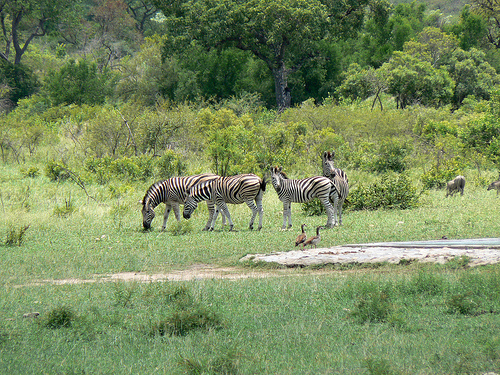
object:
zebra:
[319, 147, 351, 232]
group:
[132, 144, 365, 241]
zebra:
[265, 156, 342, 234]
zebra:
[182, 171, 271, 234]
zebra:
[135, 171, 224, 236]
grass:
[0, 163, 499, 374]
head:
[136, 201, 160, 236]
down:
[136, 201, 162, 234]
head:
[265, 164, 291, 197]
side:
[264, 168, 338, 231]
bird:
[291, 218, 308, 248]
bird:
[301, 222, 330, 257]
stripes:
[210, 179, 248, 198]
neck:
[298, 226, 307, 236]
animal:
[441, 174, 469, 198]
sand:
[0, 259, 367, 290]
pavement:
[237, 236, 500, 271]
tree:
[161, 0, 376, 115]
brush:
[1, 1, 498, 184]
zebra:
[434, 170, 471, 200]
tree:
[371, 22, 500, 114]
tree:
[194, 105, 260, 174]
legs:
[281, 202, 291, 231]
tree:
[0, 0, 61, 107]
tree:
[117, 0, 170, 51]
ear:
[323, 151, 327, 161]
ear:
[328, 151, 333, 159]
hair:
[141, 172, 169, 212]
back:
[143, 167, 212, 209]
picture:
[1, 1, 500, 371]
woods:
[2, 1, 500, 104]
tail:
[330, 181, 354, 202]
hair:
[335, 195, 345, 203]